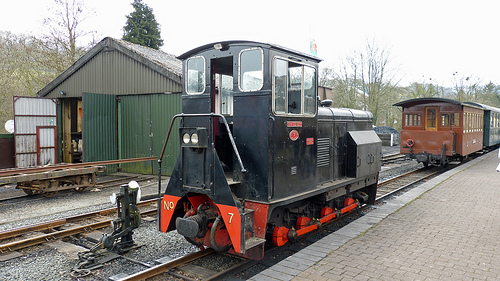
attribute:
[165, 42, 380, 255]
train — black, red, brown, metal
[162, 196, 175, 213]
letters — gold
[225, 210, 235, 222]
numbers — gold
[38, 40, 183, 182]
building — green, metal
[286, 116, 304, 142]
letters — red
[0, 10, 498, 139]
trees — green, brown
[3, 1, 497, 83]
sky — white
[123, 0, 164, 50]
tree — pine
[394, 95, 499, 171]
traincar — brown, blue, metal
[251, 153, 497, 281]
sidewalk — bricks, brown, gray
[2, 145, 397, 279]
gravel — gray